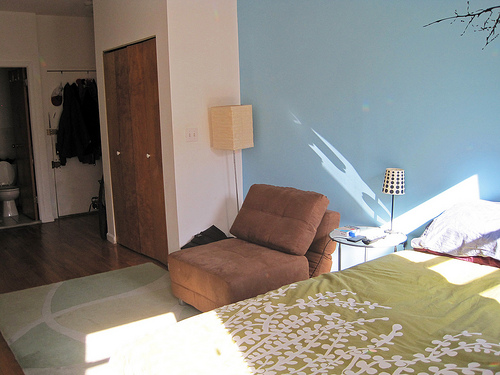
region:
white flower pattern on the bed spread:
[221, 291, 494, 373]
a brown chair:
[167, 178, 334, 310]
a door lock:
[44, 129, 56, 135]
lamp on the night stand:
[381, 165, 402, 235]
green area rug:
[1, 262, 214, 372]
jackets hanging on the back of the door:
[52, 76, 102, 166]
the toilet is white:
[0, 153, 25, 218]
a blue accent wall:
[236, 0, 496, 251]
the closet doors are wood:
[100, 35, 165, 261]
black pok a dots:
[382, 167, 404, 194]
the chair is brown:
[183, 187, 328, 324]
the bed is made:
[280, 202, 467, 371]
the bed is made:
[251, 216, 468, 369]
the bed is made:
[265, 215, 497, 363]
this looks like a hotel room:
[1, 3, 498, 373]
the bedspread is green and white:
[64, 243, 499, 374]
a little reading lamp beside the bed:
[378, 160, 411, 241]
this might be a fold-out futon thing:
[163, 178, 345, 313]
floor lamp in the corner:
[205, 96, 263, 237]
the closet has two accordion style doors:
[96, 27, 176, 270]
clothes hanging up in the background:
[49, 65, 108, 168]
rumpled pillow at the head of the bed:
[406, 191, 499, 267]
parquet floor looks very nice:
[3, 210, 149, 295]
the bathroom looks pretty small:
[2, 55, 52, 235]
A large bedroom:
[11, 10, 483, 358]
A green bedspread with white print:
[175, 256, 498, 374]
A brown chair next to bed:
[191, 197, 329, 274]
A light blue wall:
[270, 36, 476, 168]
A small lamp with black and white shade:
[368, 144, 410, 244]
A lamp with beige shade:
[198, 89, 251, 214]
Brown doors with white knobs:
[96, 39, 172, 275]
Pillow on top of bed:
[403, 194, 490, 265]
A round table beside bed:
[326, 221, 388, 262]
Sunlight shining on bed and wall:
[316, 132, 483, 280]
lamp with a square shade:
[208, 102, 253, 210]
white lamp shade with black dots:
[382, 164, 404, 216]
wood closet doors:
[103, 37, 169, 264]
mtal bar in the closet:
[45, 66, 98, 73]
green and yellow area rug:
[1, 259, 198, 372]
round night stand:
[330, 224, 407, 273]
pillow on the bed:
[411, 194, 496, 259]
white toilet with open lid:
[1, 158, 18, 218]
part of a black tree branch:
[424, 2, 499, 44]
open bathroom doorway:
[2, 68, 35, 224]